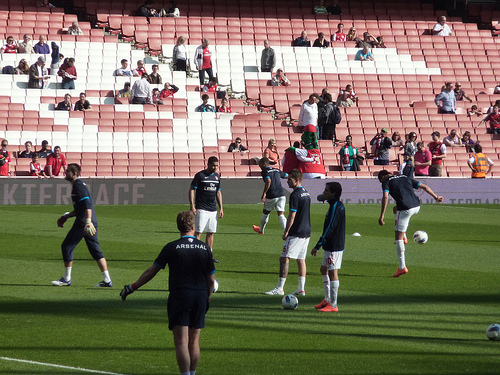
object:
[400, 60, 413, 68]
seat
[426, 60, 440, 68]
seat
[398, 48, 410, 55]
seat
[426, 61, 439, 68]
seat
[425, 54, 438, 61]
seat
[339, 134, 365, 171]
audience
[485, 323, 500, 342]
ball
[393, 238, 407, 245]
foot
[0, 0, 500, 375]
field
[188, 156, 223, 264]
man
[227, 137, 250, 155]
man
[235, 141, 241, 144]
black sunglasses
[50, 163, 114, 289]
man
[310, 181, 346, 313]
man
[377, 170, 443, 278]
man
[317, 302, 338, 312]
orange shoes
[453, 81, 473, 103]
person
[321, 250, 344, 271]
white shorts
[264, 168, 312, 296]
man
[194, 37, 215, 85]
person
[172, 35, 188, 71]
person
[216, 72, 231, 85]
seat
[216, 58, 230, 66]
seat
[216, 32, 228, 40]
seat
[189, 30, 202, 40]
seat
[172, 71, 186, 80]
seat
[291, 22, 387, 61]
crowd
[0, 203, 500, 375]
astroturf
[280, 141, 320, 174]
people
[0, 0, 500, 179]
bunch seats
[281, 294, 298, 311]
ball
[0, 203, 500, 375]
ground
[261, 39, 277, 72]
man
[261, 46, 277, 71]
jacket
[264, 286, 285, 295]
white shoe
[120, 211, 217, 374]
man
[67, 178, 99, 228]
t-shirt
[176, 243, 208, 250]
name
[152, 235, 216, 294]
shirt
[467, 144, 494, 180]
person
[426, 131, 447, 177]
person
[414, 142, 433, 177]
person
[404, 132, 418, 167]
person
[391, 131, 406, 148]
person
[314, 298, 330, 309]
shoe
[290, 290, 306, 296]
shoe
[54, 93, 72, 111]
people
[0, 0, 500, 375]
air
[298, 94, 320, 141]
people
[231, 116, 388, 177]
stands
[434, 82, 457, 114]
mascot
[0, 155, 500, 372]
soccer game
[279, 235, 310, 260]
shorts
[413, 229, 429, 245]
ball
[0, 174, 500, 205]
wall